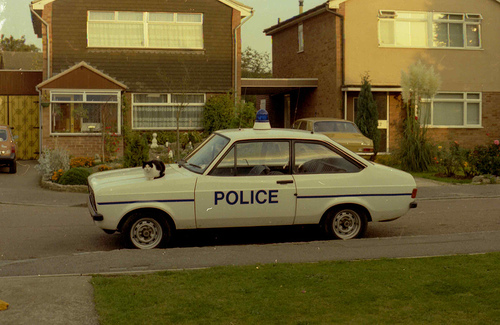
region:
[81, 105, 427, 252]
The police car is parked.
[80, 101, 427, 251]
Police car has blue light on roof of car.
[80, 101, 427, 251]
A cat is sitting on the police car.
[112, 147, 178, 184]
The cat is black and white.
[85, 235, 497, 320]
The grass is green.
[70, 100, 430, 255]
Police car is older model car.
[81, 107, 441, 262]
Police car is white.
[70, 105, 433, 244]
Blue stripe on police car.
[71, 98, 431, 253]
The police car is empty.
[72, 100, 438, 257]
Police car is unoccupied.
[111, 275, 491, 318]
The patch of a grass is short and green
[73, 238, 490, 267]
The sidewalk is made of concrete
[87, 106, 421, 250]
The police car is parked on the street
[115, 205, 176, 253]
The front tire of the police car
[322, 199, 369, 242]
The back tire of the police car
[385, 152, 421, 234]
The tail of the police car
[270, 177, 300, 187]
The handle to the car door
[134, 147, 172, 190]
A cat sitting on top of the car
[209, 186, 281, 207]
The name on the car door says "Police"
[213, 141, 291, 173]
The window on the side of the car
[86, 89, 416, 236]
car on the street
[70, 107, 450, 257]
the car is parked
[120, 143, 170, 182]
the cat on the car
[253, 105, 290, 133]
the light on top of the car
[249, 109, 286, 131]
the light is blue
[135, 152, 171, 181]
the cat is black and white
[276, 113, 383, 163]
the green car in the driveway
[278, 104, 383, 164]
the green car is parked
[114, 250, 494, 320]
the grass beside the car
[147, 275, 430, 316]
the grass is short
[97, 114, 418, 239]
white police car parked on street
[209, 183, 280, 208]
black lettering on white car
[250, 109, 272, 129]
blue light on roof of car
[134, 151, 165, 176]
cat sitting on police car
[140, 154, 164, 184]
black and white car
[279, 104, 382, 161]
car in driveway of house across street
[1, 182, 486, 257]
street white car is parked on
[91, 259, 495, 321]
patch of grass beside roadway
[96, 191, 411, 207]
black stripe down white car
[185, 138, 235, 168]
front windshield of car